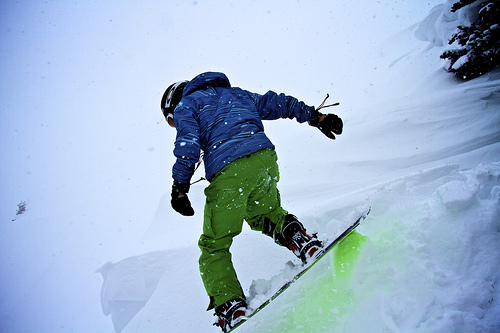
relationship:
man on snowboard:
[161, 72, 341, 332] [206, 222, 362, 332]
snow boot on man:
[276, 218, 328, 263] [155, 62, 316, 288]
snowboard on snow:
[206, 222, 362, 332] [1, 63, 463, 325]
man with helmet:
[155, 62, 316, 288] [157, 81, 194, 133]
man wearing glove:
[155, 62, 316, 288] [313, 111, 343, 140]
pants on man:
[206, 172, 277, 264] [155, 62, 316, 288]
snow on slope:
[1, 63, 463, 325] [100, 0, 499, 333]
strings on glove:
[311, 87, 338, 112] [313, 111, 343, 140]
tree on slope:
[438, 6, 495, 72] [100, 0, 499, 333]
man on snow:
[161, 72, 341, 332] [1, 63, 463, 325]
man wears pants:
[161, 72, 341, 332] [206, 172, 277, 264]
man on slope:
[161, 72, 341, 332] [15, 100, 465, 332]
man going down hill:
[161, 72, 341, 332] [27, 66, 482, 330]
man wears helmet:
[161, 72, 341, 332] [157, 81, 194, 133]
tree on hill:
[438, 6, 495, 72] [27, 66, 482, 330]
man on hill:
[161, 72, 341, 332] [93, 0, 500, 333]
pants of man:
[206, 172, 277, 264] [161, 72, 341, 332]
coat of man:
[190, 81, 271, 151] [161, 72, 341, 332]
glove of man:
[313, 111, 343, 140] [161, 72, 341, 332]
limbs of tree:
[441, 47, 472, 60] [438, 6, 495, 72]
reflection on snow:
[253, 244, 378, 323] [1, 63, 463, 325]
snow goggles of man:
[165, 107, 178, 125] [161, 72, 341, 332]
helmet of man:
[157, 81, 194, 133] [161, 72, 341, 332]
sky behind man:
[4, 11, 144, 107] [161, 72, 341, 332]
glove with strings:
[313, 111, 343, 140] [311, 87, 338, 112]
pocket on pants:
[200, 206, 223, 237] [206, 172, 277, 264]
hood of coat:
[175, 63, 234, 95] [172, 72, 312, 180]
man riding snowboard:
[161, 72, 341, 332] [206, 222, 362, 332]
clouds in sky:
[15, 17, 159, 115] [4, 11, 144, 107]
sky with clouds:
[4, 11, 144, 107] [15, 17, 159, 115]